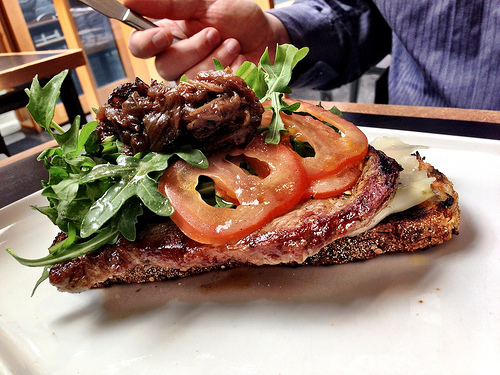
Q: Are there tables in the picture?
A: Yes, there is a table.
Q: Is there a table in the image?
A: Yes, there is a table.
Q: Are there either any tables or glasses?
A: Yes, there is a table.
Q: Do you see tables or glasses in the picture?
A: Yes, there is a table.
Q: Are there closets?
A: No, there are no closets.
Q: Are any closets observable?
A: No, there are no closets.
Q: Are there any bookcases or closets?
A: No, there are no closets or bookcases.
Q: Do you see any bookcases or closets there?
A: No, there are no closets or bookcases.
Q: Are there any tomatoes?
A: Yes, there is a tomato.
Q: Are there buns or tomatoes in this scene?
A: Yes, there is a tomato.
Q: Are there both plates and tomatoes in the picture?
A: Yes, there are both a tomato and a plate.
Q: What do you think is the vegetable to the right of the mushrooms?
A: The vegetable is a tomato.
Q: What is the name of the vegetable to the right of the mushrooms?
A: The vegetable is a tomato.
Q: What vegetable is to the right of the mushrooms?
A: The vegetable is a tomato.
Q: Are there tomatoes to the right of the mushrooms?
A: Yes, there is a tomato to the right of the mushrooms.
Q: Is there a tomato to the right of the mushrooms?
A: Yes, there is a tomato to the right of the mushrooms.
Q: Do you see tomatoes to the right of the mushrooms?
A: Yes, there is a tomato to the right of the mushrooms.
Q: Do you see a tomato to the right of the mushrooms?
A: Yes, there is a tomato to the right of the mushrooms.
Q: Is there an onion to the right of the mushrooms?
A: No, there is a tomato to the right of the mushrooms.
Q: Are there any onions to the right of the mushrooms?
A: No, there is a tomato to the right of the mushrooms.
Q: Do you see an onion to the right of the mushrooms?
A: No, there is a tomato to the right of the mushrooms.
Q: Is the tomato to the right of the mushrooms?
A: Yes, the tomato is to the right of the mushrooms.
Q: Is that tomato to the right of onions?
A: No, the tomato is to the right of the mushrooms.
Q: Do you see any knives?
A: Yes, there is a knife.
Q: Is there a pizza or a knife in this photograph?
A: Yes, there is a knife.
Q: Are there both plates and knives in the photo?
A: Yes, there are both a knife and a plate.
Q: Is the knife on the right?
A: No, the knife is on the left of the image.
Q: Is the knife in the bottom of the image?
A: No, the knife is in the top of the image.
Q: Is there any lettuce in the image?
A: Yes, there is lettuce.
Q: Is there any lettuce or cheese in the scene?
A: Yes, there is lettuce.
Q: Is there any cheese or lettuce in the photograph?
A: Yes, there is lettuce.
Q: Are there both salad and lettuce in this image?
A: No, there is lettuce but no salad.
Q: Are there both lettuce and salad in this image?
A: No, there is lettuce but no salad.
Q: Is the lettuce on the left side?
A: Yes, the lettuce is on the left of the image.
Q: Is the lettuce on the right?
A: No, the lettuce is on the left of the image.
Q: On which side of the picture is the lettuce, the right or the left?
A: The lettuce is on the left of the image.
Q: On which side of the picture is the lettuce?
A: The lettuce is on the left of the image.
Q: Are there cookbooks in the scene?
A: No, there are no cookbooks.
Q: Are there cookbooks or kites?
A: No, there are no cookbooks or kites.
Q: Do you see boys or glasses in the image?
A: No, there are no glasses or boys.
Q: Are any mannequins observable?
A: No, there are no mannequins.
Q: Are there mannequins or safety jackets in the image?
A: No, there are no mannequins or safety jackets.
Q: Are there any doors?
A: Yes, there is a door.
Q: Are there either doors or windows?
A: Yes, there is a door.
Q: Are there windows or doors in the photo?
A: Yes, there is a door.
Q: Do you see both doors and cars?
A: No, there is a door but no cars.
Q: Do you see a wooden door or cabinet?
A: Yes, there is a wood door.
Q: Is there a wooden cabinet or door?
A: Yes, there is a wood door.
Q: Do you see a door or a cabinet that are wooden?
A: Yes, the door is wooden.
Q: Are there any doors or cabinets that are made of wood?
A: Yes, the door is made of wood.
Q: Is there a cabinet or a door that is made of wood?
A: Yes, the door is made of wood.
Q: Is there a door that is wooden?
A: Yes, there is a wood door.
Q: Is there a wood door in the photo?
A: Yes, there is a wood door.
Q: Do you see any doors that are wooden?
A: Yes, there is a wood door.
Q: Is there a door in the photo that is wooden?
A: Yes, there is a door that is wooden.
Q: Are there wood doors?
A: Yes, there is a door that is made of wood.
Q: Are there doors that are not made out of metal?
A: Yes, there is a door that is made of wood.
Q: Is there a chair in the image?
A: No, there are no chairs.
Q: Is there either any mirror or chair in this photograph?
A: No, there are no chairs or mirrors.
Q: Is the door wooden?
A: Yes, the door is wooden.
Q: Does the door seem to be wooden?
A: Yes, the door is wooden.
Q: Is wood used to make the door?
A: Yes, the door is made of wood.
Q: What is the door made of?
A: The door is made of wood.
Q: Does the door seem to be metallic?
A: No, the door is wooden.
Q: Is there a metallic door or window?
A: No, there is a door but it is wooden.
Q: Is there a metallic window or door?
A: No, there is a door but it is wooden.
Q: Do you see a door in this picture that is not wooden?
A: No, there is a door but it is wooden.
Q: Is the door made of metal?
A: No, the door is made of wood.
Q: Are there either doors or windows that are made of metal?
A: No, there is a door but it is made of wood.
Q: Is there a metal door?
A: No, there is a door but it is made of wood.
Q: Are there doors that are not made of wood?
A: No, there is a door but it is made of wood.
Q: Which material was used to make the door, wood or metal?
A: The door is made of wood.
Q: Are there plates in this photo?
A: Yes, there is a plate.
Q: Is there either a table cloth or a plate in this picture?
A: Yes, there is a plate.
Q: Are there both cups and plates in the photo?
A: No, there is a plate but no cups.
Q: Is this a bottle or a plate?
A: This is a plate.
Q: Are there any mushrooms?
A: Yes, there are mushrooms.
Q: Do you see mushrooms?
A: Yes, there are mushrooms.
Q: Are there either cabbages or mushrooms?
A: Yes, there are mushrooms.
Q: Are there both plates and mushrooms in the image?
A: Yes, there are both mushrooms and a plate.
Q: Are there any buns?
A: No, there are no buns.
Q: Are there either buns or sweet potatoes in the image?
A: No, there are no buns or sweet potatoes.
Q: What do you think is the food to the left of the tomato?
A: The food is mushrooms.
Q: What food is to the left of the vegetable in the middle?
A: The food is mushrooms.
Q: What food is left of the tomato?
A: The food is mushrooms.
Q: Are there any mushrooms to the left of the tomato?
A: Yes, there are mushrooms to the left of the tomato.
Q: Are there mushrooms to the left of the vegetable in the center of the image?
A: Yes, there are mushrooms to the left of the tomato.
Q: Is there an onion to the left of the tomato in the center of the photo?
A: No, there are mushrooms to the left of the tomato.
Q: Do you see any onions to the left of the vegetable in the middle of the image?
A: No, there are mushrooms to the left of the tomato.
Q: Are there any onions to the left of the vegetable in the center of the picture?
A: No, there are mushrooms to the left of the tomato.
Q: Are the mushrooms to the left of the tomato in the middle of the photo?
A: Yes, the mushrooms are to the left of the tomato.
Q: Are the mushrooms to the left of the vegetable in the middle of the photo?
A: Yes, the mushrooms are to the left of the tomato.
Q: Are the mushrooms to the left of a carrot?
A: No, the mushrooms are to the left of the tomato.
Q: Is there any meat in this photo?
A: Yes, there is meat.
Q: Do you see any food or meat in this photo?
A: Yes, there is meat.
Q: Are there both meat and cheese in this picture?
A: Yes, there are both meat and cheese.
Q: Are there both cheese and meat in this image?
A: Yes, there are both meat and cheese.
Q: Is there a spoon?
A: No, there are no spoons.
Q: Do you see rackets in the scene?
A: No, there are no rackets.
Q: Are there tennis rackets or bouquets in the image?
A: No, there are no tennis rackets or bouquets.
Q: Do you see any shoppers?
A: No, there are no shoppers.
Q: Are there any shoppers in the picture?
A: No, there are no shoppers.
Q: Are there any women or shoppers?
A: No, there are no shoppers or women.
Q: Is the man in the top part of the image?
A: Yes, the man is in the top of the image.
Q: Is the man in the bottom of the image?
A: No, the man is in the top of the image.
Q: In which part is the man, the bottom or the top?
A: The man is in the top of the image.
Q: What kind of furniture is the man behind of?
A: The man is behind the table.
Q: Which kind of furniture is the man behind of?
A: The man is behind the table.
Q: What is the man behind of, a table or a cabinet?
A: The man is behind a table.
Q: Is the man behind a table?
A: Yes, the man is behind a table.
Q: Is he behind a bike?
A: No, the man is behind a table.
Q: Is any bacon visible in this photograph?
A: Yes, there is bacon.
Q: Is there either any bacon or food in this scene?
A: Yes, there is bacon.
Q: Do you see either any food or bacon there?
A: Yes, there is bacon.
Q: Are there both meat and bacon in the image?
A: Yes, there are both bacon and meat.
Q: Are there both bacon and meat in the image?
A: Yes, there are both bacon and meat.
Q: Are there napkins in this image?
A: No, there are no napkins.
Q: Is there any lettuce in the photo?
A: Yes, there is lettuce.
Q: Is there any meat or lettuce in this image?
A: Yes, there is lettuce.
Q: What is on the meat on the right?
A: The lettuce is on the meat.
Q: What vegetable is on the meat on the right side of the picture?
A: The vegetable is lettuce.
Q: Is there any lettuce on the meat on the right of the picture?
A: Yes, there is lettuce on the meat.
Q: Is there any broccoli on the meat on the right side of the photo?
A: No, there is lettuce on the meat.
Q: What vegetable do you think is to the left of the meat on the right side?
A: The vegetable is lettuce.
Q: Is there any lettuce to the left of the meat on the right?
A: Yes, there is lettuce to the left of the meat.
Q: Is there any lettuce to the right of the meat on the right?
A: No, the lettuce is to the left of the meat.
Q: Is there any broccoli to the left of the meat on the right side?
A: No, there is lettuce to the left of the meat.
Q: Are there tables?
A: Yes, there is a table.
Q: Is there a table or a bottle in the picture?
A: Yes, there is a table.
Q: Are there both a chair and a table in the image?
A: No, there is a table but no chairs.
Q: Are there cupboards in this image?
A: No, there are no cupboards.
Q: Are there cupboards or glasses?
A: No, there are no cupboards or glasses.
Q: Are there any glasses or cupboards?
A: No, there are no cupboards or glasses.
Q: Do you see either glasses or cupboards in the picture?
A: No, there are no cupboards or glasses.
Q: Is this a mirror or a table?
A: This is a table.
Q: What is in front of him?
A: The table is in front of the man.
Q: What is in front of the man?
A: The table is in front of the man.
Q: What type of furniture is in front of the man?
A: The piece of furniture is a table.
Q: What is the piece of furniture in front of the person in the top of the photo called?
A: The piece of furniture is a table.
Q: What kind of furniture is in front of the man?
A: The piece of furniture is a table.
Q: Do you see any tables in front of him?
A: Yes, there is a table in front of the man.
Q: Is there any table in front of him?
A: Yes, there is a table in front of the man.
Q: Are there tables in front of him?
A: Yes, there is a table in front of the man.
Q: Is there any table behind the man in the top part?
A: No, the table is in front of the man.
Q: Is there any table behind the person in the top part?
A: No, the table is in front of the man.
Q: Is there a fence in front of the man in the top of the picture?
A: No, there is a table in front of the man.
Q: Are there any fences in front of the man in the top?
A: No, there is a table in front of the man.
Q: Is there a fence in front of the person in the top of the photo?
A: No, there is a table in front of the man.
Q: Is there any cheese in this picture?
A: Yes, there is cheese.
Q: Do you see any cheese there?
A: Yes, there is cheese.